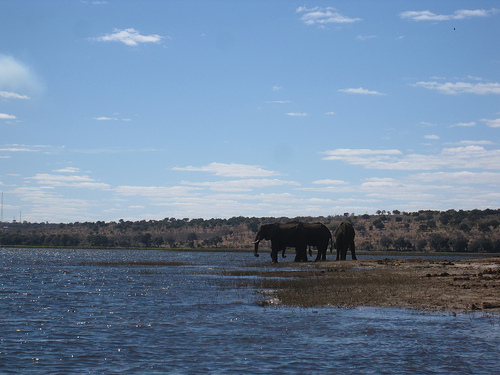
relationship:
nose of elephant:
[252, 238, 260, 259] [234, 214, 307, 264]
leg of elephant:
[348, 237, 356, 259] [326, 220, 365, 263]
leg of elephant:
[271, 240, 281, 260] [250, 220, 311, 274]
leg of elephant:
[315, 243, 322, 261] [295, 213, 335, 260]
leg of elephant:
[315, 245, 322, 257] [298, 219, 344, 265]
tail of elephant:
[325, 228, 336, 252] [304, 214, 338, 267]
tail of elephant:
[324, 229, 334, 253] [326, 222, 336, 254]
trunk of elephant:
[252, 237, 264, 266] [249, 220, 309, 262]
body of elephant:
[242, 212, 316, 263] [269, 220, 301, 247]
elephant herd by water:
[251, 218, 359, 264] [2, 247, 497, 373]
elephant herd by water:
[242, 209, 371, 279] [2, 247, 497, 373]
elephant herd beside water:
[251, 218, 359, 264] [2, 247, 497, 373]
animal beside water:
[248, 222, 313, 266] [2, 247, 497, 373]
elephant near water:
[280, 217, 337, 263] [2, 247, 497, 373]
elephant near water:
[330, 220, 358, 261] [2, 247, 497, 373]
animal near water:
[248, 222, 313, 266] [2, 247, 497, 373]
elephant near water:
[272, 217, 335, 270] [2, 247, 497, 373]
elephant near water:
[330, 220, 362, 270] [2, 247, 497, 373]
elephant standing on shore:
[280, 217, 337, 263] [2, 233, 499, 271]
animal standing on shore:
[248, 222, 313, 266] [2, 233, 499, 271]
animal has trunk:
[248, 222, 313, 266] [249, 237, 261, 262]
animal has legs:
[248, 222, 313, 266] [265, 243, 281, 269]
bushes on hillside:
[3, 205, 499, 253] [0, 207, 498, 257]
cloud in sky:
[338, 85, 384, 99] [2, 1, 498, 221]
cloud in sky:
[418, 73, 498, 97] [2, 1, 498, 221]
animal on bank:
[248, 222, 313, 266] [207, 248, 498, 319]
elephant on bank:
[280, 217, 337, 263] [207, 248, 498, 319]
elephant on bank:
[330, 220, 358, 261] [207, 248, 498, 319]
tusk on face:
[248, 235, 258, 246] [248, 220, 267, 261]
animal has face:
[248, 222, 313, 266] [248, 220, 267, 261]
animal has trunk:
[248, 222, 313, 266] [250, 231, 262, 261]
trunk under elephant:
[276, 238, 289, 259] [272, 221, 338, 265]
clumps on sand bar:
[413, 257, 498, 307] [248, 255, 498, 316]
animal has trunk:
[242, 214, 312, 264] [248, 222, 268, 256]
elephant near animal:
[280, 217, 337, 263] [330, 213, 360, 262]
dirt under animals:
[241, 244, 419, 307] [246, 209, 364, 269]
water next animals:
[0, 247, 500, 373] [244, 213, 360, 265]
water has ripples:
[8, 251, 249, 358] [35, 265, 231, 357]